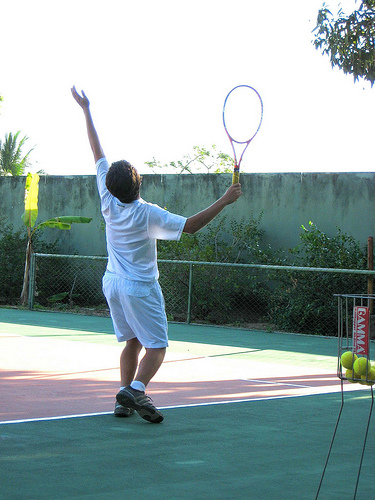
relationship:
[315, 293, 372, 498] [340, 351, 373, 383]
basket with tennis balls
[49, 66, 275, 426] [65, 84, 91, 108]
man has hand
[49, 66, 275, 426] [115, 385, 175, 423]
man has feet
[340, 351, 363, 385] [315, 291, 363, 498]
tennis balls in basket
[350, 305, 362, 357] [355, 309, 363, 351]
sign with letters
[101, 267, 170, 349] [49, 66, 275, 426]
shorts on man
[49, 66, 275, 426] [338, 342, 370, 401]
man in all white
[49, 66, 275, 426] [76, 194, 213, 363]
man serving a tennis ball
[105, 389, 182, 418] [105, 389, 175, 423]
sneakers on feet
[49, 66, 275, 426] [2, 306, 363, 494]
man on court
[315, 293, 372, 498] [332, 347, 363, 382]
basket holding balls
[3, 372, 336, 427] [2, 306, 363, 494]
line on court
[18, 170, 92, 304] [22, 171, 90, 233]
plant with leaves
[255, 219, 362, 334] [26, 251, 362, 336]
shrub behind fence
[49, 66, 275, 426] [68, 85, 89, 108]
man with hand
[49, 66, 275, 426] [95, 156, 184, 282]
man wearing shirt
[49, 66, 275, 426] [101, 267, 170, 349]
man wearing shorts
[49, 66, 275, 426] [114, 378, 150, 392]
man wearing socks